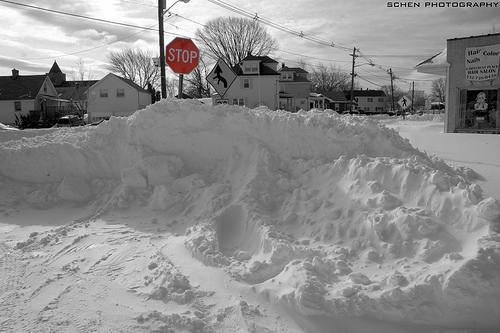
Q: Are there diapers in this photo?
A: No, there are no diapers.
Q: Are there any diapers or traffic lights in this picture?
A: No, there are no diapers or traffic lights.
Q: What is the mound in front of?
A: The mound is in front of the stop sign.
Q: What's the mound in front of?
A: The mound is in front of the stop sign.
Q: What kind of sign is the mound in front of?
A: The mound is in front of the stop sign.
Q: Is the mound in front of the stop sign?
A: Yes, the mound is in front of the stop sign.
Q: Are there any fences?
A: No, there are no fences.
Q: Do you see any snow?
A: Yes, there is snow.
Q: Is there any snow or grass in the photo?
A: Yes, there is snow.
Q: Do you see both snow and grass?
A: No, there is snow but no grass.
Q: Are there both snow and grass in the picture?
A: No, there is snow but no grass.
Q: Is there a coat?
A: No, there are no coats.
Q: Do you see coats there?
A: No, there are no coats.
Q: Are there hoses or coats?
A: No, there are no coats or hoses.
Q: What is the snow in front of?
A: The snow is in front of the stop sign.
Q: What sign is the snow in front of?
A: The snow is in front of the stop sign.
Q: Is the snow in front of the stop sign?
A: Yes, the snow is in front of the stop sign.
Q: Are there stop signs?
A: Yes, there is a stop sign.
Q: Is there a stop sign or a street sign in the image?
A: Yes, there is a stop sign.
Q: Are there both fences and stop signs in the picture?
A: No, there is a stop sign but no fences.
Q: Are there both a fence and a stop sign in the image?
A: No, there is a stop sign but no fences.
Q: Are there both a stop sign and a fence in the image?
A: No, there is a stop sign but no fences.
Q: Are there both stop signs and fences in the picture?
A: No, there is a stop sign but no fences.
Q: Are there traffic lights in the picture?
A: No, there are no traffic lights.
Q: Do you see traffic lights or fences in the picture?
A: No, there are no traffic lights or fences.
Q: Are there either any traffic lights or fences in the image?
A: No, there are no traffic lights or fences.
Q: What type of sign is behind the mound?
A: The sign is a stop sign.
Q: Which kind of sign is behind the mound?
A: The sign is a stop sign.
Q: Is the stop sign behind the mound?
A: Yes, the stop sign is behind the mound.